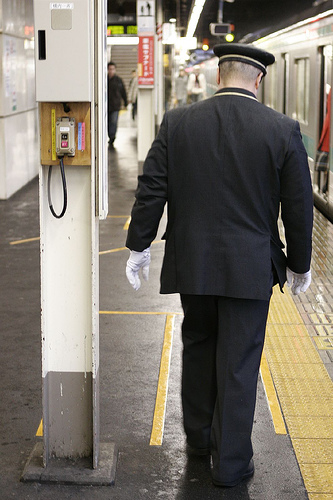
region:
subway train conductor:
[122, 31, 319, 303]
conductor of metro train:
[143, 40, 306, 394]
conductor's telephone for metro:
[13, 71, 118, 221]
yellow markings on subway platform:
[133, 294, 329, 482]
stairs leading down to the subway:
[105, 9, 167, 150]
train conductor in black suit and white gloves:
[131, 31, 327, 317]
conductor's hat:
[200, 33, 274, 101]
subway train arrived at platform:
[181, 10, 332, 215]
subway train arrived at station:
[163, 14, 329, 221]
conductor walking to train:
[167, 20, 311, 150]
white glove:
[121, 238, 159, 296]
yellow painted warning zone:
[255, 281, 331, 498]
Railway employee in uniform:
[130, 33, 315, 453]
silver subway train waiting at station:
[174, 7, 329, 194]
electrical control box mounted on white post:
[22, 1, 101, 172]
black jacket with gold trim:
[122, 79, 328, 295]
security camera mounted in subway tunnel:
[204, 4, 234, 37]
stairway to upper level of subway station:
[109, 36, 142, 107]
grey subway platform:
[6, 126, 329, 487]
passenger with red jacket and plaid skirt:
[315, 79, 332, 178]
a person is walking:
[120, 34, 312, 488]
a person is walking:
[104, 60, 131, 144]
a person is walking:
[187, 64, 208, 111]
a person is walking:
[171, 67, 187, 106]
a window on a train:
[293, 56, 306, 123]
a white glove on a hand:
[123, 241, 151, 294]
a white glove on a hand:
[284, 264, 310, 296]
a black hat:
[209, 36, 276, 76]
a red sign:
[137, 34, 153, 89]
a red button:
[59, 139, 69, 148]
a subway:
[15, 8, 329, 497]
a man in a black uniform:
[124, 49, 316, 488]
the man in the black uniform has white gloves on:
[123, 45, 309, 487]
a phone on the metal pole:
[37, 96, 94, 215]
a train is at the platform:
[188, 5, 331, 333]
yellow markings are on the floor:
[100, 173, 329, 497]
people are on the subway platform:
[103, 59, 212, 151]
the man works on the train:
[124, 32, 317, 491]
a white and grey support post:
[32, 29, 117, 490]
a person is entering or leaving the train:
[314, 64, 332, 211]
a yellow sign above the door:
[106, 23, 135, 37]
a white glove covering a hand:
[120, 247, 152, 285]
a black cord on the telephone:
[47, 161, 69, 219]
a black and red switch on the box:
[54, 117, 78, 156]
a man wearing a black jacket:
[107, 62, 128, 147]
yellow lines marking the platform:
[147, 308, 166, 444]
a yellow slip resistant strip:
[282, 363, 322, 420]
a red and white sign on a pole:
[132, 32, 163, 92]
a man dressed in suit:
[129, 41, 324, 447]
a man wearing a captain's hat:
[122, 38, 319, 483]